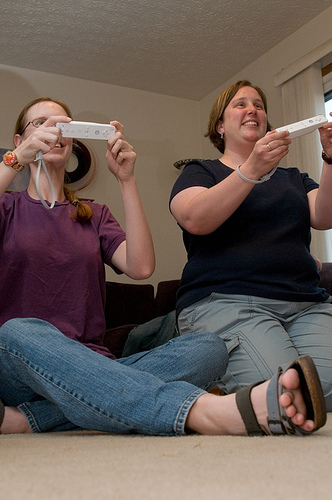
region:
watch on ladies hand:
[1, 136, 34, 161]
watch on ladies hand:
[0, 145, 47, 179]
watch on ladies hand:
[6, 145, 22, 167]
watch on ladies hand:
[0, 150, 57, 197]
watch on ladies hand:
[0, 149, 30, 175]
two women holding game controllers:
[0, 73, 329, 216]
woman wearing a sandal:
[234, 349, 327, 440]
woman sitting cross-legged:
[4, 316, 230, 441]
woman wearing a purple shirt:
[1, 132, 127, 352]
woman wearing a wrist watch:
[0, 138, 41, 183]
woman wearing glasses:
[10, 116, 70, 141]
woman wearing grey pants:
[177, 288, 331, 408]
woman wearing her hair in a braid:
[10, 95, 97, 226]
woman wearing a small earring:
[211, 118, 228, 144]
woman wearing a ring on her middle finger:
[257, 127, 293, 170]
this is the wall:
[135, 108, 162, 133]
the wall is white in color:
[140, 144, 164, 180]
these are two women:
[12, 79, 331, 413]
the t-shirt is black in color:
[259, 206, 280, 239]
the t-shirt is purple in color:
[16, 231, 75, 302]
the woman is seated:
[7, 286, 230, 387]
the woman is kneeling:
[220, 319, 328, 397]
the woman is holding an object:
[52, 121, 120, 137]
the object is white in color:
[82, 121, 96, 132]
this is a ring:
[261, 141, 276, 151]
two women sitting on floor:
[10, 67, 326, 439]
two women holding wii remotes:
[23, 87, 328, 165]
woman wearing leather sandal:
[216, 350, 326, 450]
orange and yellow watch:
[1, 142, 26, 177]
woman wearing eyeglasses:
[16, 110, 80, 146]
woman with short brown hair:
[204, 67, 277, 156]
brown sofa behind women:
[107, 272, 186, 338]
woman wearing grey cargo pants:
[168, 278, 331, 391]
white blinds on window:
[269, 63, 331, 217]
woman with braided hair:
[39, 170, 101, 229]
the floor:
[193, 467, 217, 491]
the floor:
[207, 479, 234, 498]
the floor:
[170, 452, 216, 496]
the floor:
[186, 441, 223, 492]